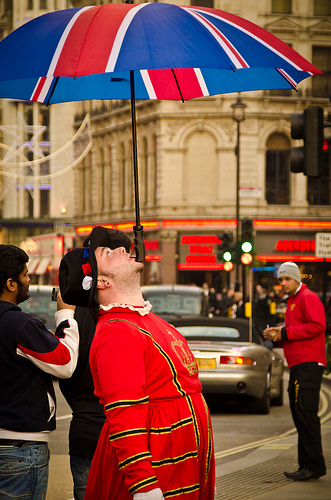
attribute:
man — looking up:
[58, 245, 224, 498]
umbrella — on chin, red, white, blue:
[0, 3, 323, 106]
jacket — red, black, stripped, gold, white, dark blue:
[84, 301, 217, 499]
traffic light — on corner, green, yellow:
[219, 217, 257, 274]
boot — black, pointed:
[282, 462, 330, 484]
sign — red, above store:
[176, 234, 229, 271]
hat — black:
[57, 225, 109, 324]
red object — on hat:
[81, 262, 92, 275]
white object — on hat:
[81, 275, 94, 291]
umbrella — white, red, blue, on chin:
[2, 3, 325, 266]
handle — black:
[125, 71, 148, 262]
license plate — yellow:
[195, 356, 218, 371]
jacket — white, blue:
[0, 299, 82, 443]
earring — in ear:
[104, 280, 112, 287]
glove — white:
[129, 484, 168, 498]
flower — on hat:
[82, 248, 90, 260]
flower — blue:
[83, 248, 91, 260]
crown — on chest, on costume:
[167, 327, 201, 375]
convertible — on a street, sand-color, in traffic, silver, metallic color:
[164, 317, 287, 413]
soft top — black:
[166, 316, 277, 345]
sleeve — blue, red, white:
[17, 310, 81, 379]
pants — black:
[284, 362, 327, 469]